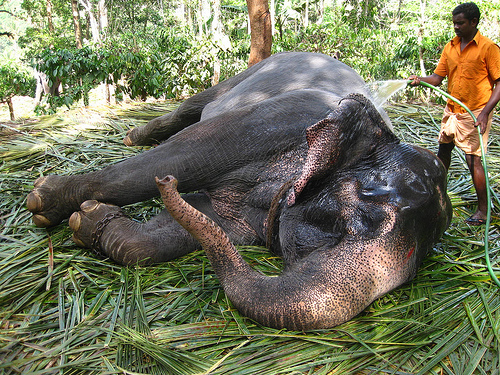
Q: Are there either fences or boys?
A: No, there are no fences or boys.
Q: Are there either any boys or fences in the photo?
A: No, there are no fences or boys.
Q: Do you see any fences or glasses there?
A: No, there are no fences or glasses.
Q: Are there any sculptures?
A: No, there are no sculptures.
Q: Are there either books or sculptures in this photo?
A: No, there are no sculptures or books.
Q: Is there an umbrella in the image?
A: No, there are no umbrellas.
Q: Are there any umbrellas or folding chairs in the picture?
A: No, there are no umbrellas or folding chairs.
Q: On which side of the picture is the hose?
A: The hose is on the right of the image.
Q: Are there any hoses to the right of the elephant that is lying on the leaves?
A: Yes, there is a hose to the right of the elephant.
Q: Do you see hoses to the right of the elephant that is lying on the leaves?
A: Yes, there is a hose to the right of the elephant.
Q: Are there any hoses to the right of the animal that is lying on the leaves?
A: Yes, there is a hose to the right of the elephant.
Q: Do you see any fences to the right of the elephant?
A: No, there is a hose to the right of the elephant.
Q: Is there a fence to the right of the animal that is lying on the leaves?
A: No, there is a hose to the right of the elephant.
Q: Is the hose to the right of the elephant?
A: Yes, the hose is to the right of the elephant.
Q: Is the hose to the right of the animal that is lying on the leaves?
A: Yes, the hose is to the right of the elephant.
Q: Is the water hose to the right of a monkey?
A: No, the water hose is to the right of the elephant.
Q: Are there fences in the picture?
A: No, there are no fences.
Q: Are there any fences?
A: No, there are no fences.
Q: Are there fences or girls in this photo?
A: No, there are no fences or girls.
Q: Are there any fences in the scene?
A: No, there are no fences.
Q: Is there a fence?
A: No, there are no fences.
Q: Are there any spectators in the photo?
A: No, there are no spectators.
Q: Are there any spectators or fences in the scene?
A: No, there are no spectators or fences.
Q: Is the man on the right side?
A: Yes, the man is on the right of the image.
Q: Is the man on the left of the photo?
A: No, the man is on the right of the image.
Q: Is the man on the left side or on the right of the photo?
A: The man is on the right of the image.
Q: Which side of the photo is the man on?
A: The man is on the right of the image.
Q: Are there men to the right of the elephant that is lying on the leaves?
A: Yes, there is a man to the right of the elephant.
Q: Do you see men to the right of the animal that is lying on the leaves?
A: Yes, there is a man to the right of the elephant.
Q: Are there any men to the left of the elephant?
A: No, the man is to the right of the elephant.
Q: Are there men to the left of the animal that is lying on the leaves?
A: No, the man is to the right of the elephant.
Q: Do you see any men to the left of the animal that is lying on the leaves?
A: No, the man is to the right of the elephant.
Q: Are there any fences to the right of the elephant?
A: No, there is a man to the right of the elephant.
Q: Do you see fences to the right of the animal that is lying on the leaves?
A: No, there is a man to the right of the elephant.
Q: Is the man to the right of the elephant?
A: Yes, the man is to the right of the elephant.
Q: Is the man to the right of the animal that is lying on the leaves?
A: Yes, the man is to the right of the elephant.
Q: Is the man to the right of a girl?
A: No, the man is to the right of the elephant.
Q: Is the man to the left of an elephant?
A: No, the man is to the right of an elephant.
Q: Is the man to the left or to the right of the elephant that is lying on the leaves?
A: The man is to the right of the elephant.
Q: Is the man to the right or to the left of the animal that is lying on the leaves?
A: The man is to the right of the elephant.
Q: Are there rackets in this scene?
A: No, there are no rackets.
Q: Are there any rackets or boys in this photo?
A: No, there are no rackets or boys.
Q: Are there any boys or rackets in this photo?
A: No, there are no rackets or boys.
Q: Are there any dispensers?
A: No, there are no dispensers.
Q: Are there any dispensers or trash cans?
A: No, there are no dispensers or trash cans.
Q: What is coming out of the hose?
A: The water is coming out of the hose.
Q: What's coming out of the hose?
A: The water is coming out of the hose.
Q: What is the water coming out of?
A: The water is coming out of the hose.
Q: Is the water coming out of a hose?
A: Yes, the water is coming out of a hose.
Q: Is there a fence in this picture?
A: No, there are no fences.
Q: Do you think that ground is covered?
A: Yes, the ground is covered.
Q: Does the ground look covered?
A: Yes, the ground is covered.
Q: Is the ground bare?
A: No, the ground is covered.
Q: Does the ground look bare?
A: No, the ground is covered.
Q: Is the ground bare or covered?
A: The ground is covered.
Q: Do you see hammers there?
A: No, there are no hammers.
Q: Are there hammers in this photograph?
A: No, there are no hammers.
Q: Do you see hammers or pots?
A: No, there are no hammers or pots.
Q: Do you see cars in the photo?
A: No, there are no cars.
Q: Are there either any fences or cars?
A: No, there are no cars or fences.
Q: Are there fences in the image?
A: No, there are no fences.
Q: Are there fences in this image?
A: No, there are no fences.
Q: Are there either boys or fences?
A: No, there are no fences or boys.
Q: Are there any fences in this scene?
A: No, there are no fences.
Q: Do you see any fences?
A: No, there are no fences.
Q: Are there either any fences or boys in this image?
A: No, there are no fences or boys.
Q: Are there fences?
A: No, there are no fences.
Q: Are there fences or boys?
A: No, there are no fences or boys.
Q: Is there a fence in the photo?
A: No, there are no fences.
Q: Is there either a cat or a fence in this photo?
A: No, there are no fences or cats.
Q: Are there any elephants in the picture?
A: Yes, there is an elephant.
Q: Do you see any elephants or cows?
A: Yes, there is an elephant.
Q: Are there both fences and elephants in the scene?
A: No, there is an elephant but no fences.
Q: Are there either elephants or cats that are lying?
A: Yes, the elephant is lying.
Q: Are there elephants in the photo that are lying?
A: Yes, there is an elephant that is lying.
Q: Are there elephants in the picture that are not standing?
A: Yes, there is an elephant that is lying.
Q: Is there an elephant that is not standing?
A: Yes, there is an elephant that is lying.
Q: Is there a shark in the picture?
A: No, there are no sharks.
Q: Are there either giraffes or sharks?
A: No, there are no sharks or giraffes.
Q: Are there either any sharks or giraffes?
A: No, there are no sharks or giraffes.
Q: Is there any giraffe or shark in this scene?
A: No, there are no sharks or giraffes.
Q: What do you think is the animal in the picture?
A: The animal is an elephant.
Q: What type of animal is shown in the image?
A: The animal is an elephant.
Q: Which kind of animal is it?
A: The animal is an elephant.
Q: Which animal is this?
A: That is an elephant.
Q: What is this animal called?
A: That is an elephant.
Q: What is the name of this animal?
A: That is an elephant.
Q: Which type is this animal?
A: That is an elephant.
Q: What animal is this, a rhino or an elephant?
A: That is an elephant.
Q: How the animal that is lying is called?
A: The animal is an elephant.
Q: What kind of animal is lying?
A: The animal is an elephant.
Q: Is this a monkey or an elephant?
A: This is an elephant.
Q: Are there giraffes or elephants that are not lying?
A: No, there is an elephant but it is lying.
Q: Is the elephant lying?
A: Yes, the elephant is lying.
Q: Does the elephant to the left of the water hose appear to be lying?
A: Yes, the elephant is lying.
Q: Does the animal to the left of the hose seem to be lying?
A: Yes, the elephant is lying.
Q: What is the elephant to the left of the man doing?
A: The elephant is lying.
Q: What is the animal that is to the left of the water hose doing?
A: The elephant is lying.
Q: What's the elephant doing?
A: The elephant is lying.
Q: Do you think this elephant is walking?
A: No, the elephant is lying.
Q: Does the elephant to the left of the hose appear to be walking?
A: No, the elephant is lying.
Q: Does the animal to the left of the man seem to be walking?
A: No, the elephant is lying.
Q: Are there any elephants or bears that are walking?
A: No, there is an elephant but it is lying.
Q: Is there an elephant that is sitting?
A: No, there is an elephant but it is lying.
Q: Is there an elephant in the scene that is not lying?
A: No, there is an elephant but it is lying.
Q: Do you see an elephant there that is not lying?
A: No, there is an elephant but it is lying.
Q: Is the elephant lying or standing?
A: The elephant is lying.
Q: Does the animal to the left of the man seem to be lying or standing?
A: The elephant is lying.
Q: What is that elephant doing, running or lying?
A: The elephant is lying.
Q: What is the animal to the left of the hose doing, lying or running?
A: The elephant is lying.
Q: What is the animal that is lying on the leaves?
A: The animal is an elephant.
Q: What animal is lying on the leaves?
A: The animal is an elephant.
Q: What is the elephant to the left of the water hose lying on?
A: The elephant is lying on the leaves.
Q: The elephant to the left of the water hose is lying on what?
A: The elephant is lying on the leaves.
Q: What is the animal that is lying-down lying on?
A: The elephant is lying on the leaves.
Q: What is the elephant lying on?
A: The elephant is lying on the leaves.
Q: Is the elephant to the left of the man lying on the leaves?
A: Yes, the elephant is lying on the leaves.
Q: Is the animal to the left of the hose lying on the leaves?
A: Yes, the elephant is lying on the leaves.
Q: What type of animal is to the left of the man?
A: The animal is an elephant.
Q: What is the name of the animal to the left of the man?
A: The animal is an elephant.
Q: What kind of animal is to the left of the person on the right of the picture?
A: The animal is an elephant.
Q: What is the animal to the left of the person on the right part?
A: The animal is an elephant.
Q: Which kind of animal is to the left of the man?
A: The animal is an elephant.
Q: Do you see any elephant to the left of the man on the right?
A: Yes, there is an elephant to the left of the man.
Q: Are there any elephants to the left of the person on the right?
A: Yes, there is an elephant to the left of the man.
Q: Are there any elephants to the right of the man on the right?
A: No, the elephant is to the left of the man.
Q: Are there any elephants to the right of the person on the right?
A: No, the elephant is to the left of the man.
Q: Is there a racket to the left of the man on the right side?
A: No, there is an elephant to the left of the man.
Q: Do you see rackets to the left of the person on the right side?
A: No, there is an elephant to the left of the man.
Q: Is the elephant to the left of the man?
A: Yes, the elephant is to the left of the man.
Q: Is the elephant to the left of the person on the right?
A: Yes, the elephant is to the left of the man.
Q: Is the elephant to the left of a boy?
A: No, the elephant is to the left of the man.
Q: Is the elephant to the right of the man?
A: No, the elephant is to the left of the man.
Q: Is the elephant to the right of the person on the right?
A: No, the elephant is to the left of the man.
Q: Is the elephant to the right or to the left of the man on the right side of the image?
A: The elephant is to the left of the man.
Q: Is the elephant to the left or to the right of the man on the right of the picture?
A: The elephant is to the left of the man.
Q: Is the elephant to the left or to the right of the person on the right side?
A: The elephant is to the left of the man.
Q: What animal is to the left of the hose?
A: The animal is an elephant.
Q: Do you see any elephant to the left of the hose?
A: Yes, there is an elephant to the left of the hose.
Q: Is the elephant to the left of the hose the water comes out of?
A: Yes, the elephant is to the left of the water hose.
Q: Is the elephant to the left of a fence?
A: No, the elephant is to the left of the water hose.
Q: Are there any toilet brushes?
A: No, there are no toilet brushes.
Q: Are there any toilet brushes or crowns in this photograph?
A: No, there are no toilet brushes or crowns.